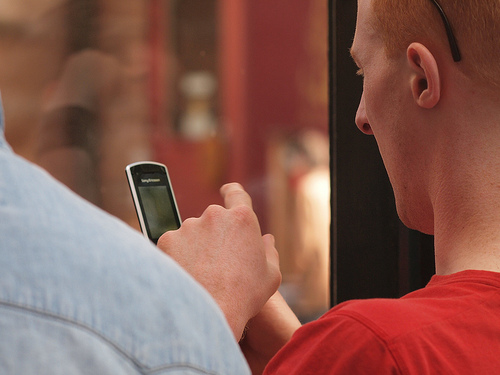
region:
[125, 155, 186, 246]
Sceen of a cell phone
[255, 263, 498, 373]
Portion of a red colored shirt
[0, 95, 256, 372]
Light blue colored shirt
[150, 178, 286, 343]
Hand pointing to a screen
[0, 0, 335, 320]
Blurry red shaded background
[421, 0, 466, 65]
End of a pair glasses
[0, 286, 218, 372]
Line of thread joint on blue shirt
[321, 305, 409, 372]
Line of thread joint on red shirt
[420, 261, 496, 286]
Neck section of a shirt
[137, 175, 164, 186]
Branding on a cell phone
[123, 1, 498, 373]
A man with a cellphone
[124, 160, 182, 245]
A cellphone in a hand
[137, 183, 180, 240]
A cellphone screen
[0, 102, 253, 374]
A light blue shirt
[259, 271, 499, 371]
A red shirt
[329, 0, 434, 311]
Dark colored frame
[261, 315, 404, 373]
Left sleeve of a shirt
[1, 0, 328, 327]
Blur background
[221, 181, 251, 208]
Left index finger of a man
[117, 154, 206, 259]
an old flip phone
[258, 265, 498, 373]
a plane red shirt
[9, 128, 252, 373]
a light colored denim jacket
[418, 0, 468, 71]
the frame of a glass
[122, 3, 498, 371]
a man looking at his phone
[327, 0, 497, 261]
a naturally red headed man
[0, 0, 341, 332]
a glass barrier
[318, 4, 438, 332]
a dark colored window frame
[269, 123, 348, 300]
a distant chef in white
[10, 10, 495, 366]
two people standing together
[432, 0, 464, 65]
one leg of a sunglasses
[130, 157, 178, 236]
a cellphone on his hand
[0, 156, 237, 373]
this shirt is blue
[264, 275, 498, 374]
the t-shirt is red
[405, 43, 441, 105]
one ear of the man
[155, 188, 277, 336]
one hand of the man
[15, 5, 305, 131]
a blurry background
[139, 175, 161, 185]
the illegible logo of the phone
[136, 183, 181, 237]
the cellphone display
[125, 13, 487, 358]
he is dialing a phone number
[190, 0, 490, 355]
man looking a cell phone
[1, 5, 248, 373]
a blue jacket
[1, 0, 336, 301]
background is blurry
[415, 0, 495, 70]
man has sunglasses on his head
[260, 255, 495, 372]
man wearing a red shirt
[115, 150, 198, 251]
older model cell phone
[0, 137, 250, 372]
light blue denim shirt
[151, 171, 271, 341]
man has hand pointed at phone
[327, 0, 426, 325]
wall or structure in front the man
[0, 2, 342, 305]
building in front of the people is out of focus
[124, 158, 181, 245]
The phone is open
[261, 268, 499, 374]
The red shirt on the man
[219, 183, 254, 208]
The finger of the man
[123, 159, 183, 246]
Silver and black cell phone top.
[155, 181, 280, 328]
Hand with finger extended.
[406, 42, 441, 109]
Left side ear on a head.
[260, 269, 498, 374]
A red shirt on a man.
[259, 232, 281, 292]
A left hand thumb.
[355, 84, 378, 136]
Nose on the face of a man.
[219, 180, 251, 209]
Finger extended out by a phone.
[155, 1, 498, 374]
Man in red shirt with orange hair.